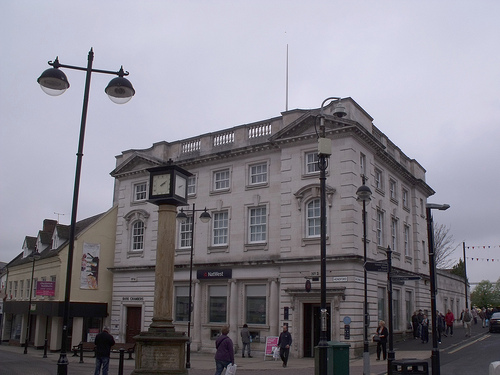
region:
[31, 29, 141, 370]
post with lights on it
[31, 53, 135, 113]
lights on a post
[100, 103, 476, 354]
building on corner of street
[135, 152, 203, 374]
tower with clock in street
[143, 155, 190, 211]
clock area in a square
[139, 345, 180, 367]
lettering on base of clock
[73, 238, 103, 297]
banner on side of building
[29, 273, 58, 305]
banner near window of building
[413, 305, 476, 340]
people on the sidewalk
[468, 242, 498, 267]
flags hanging off lines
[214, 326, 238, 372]
The woman is carrying a bag.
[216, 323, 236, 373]
The woman is carrying a white bag.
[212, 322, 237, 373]
The woman is wearing a purple jacket.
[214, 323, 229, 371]
The woman is carrying a purse.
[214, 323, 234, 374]
The woman has brown hair.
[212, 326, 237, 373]
he woman has short hair.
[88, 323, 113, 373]
The man is wearing a black jacket.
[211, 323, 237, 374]
The woman is wearing blue jeans.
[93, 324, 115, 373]
The man is wearing blue jeans.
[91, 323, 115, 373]
The man's hair is gray.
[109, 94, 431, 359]
Large building sitting on the corner of the steet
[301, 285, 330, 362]
Black front door of the building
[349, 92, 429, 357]
Side of the big building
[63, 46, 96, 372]
Black street light pole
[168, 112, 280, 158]
Railing at the top of the building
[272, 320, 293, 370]
Person crossing the street with a bag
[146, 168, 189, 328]
wood pole with a clock at the top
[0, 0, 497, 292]
Gloomy sky over the large building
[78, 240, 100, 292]
Advertisement on the side of the yellow building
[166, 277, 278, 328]
Three windows on the first floor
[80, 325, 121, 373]
this is a person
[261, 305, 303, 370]
this is a person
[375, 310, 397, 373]
this is a person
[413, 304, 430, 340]
this is a person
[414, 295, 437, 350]
this is a person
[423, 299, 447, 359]
this is a person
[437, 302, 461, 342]
this is a person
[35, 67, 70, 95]
A globe light on a pole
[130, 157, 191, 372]
A clock statue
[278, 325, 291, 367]
Man wearing a uniform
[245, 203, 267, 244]
A big window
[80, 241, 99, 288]
A banner hanging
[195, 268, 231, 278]
A building logo outside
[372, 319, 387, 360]
A lady walking by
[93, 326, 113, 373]
A man walking on the street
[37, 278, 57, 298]
A pink banner hanging on a pole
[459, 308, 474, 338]
Man wearing a suit